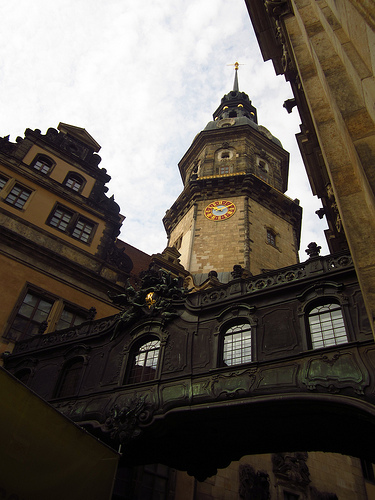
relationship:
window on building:
[47, 339, 107, 409] [6, 2, 368, 493]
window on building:
[27, 151, 58, 175] [32, 109, 269, 361]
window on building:
[27, 151, 58, 175] [0, 117, 125, 260]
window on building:
[40, 182, 103, 246] [9, 88, 361, 488]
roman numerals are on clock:
[204, 203, 234, 219] [198, 195, 244, 221]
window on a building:
[7, 282, 97, 334] [4, 113, 174, 497]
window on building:
[47, 339, 107, 409] [8, 254, 369, 429]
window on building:
[115, 328, 172, 381] [121, 72, 326, 475]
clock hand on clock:
[208, 203, 220, 213] [195, 196, 236, 227]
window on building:
[301, 292, 351, 351] [6, 2, 368, 493]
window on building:
[68, 213, 97, 246] [3, 126, 105, 297]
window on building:
[27, 151, 58, 175] [2, 117, 155, 328]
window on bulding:
[218, 315, 252, 367] [0, 0, 373, 498]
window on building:
[72, 213, 96, 244] [5, 121, 167, 361]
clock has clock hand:
[203, 200, 242, 223] [208, 203, 220, 213]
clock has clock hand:
[203, 200, 242, 223] [215, 201, 231, 213]